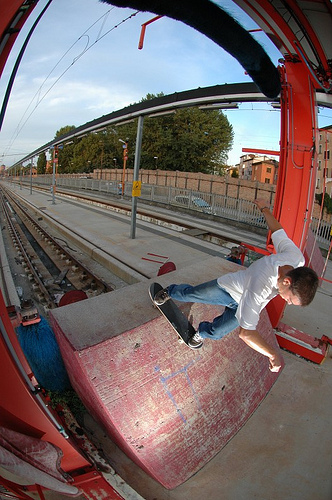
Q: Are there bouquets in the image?
A: No, there are no bouquets.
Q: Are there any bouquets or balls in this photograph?
A: No, there are no bouquets or balls.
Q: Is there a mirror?
A: No, there are no mirrors.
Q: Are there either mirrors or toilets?
A: No, there are no mirrors or toilets.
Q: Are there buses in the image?
A: No, there are no buses.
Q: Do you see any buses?
A: No, there are no buses.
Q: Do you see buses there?
A: No, there are no buses.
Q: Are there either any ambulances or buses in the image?
A: No, there are no buses or ambulances.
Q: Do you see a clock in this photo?
A: No, there are no clocks.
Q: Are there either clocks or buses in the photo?
A: No, there are no clocks or buses.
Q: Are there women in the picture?
A: No, there are no women.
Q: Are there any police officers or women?
A: No, there are no women or police officers.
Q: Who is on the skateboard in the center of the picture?
A: The boy is on the skateboard.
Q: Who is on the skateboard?
A: The boy is on the skateboard.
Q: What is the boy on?
A: The boy is on the skateboard.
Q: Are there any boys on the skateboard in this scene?
A: Yes, there is a boy on the skateboard.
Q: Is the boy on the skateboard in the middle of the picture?
A: Yes, the boy is on the skateboard.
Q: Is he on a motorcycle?
A: No, the boy is on the skateboard.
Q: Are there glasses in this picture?
A: No, there are no glasses.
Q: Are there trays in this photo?
A: No, there are no trays.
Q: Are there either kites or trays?
A: No, there are no trays or kites.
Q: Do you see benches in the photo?
A: No, there are no benches.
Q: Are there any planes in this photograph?
A: No, there are no planes.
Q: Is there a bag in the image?
A: No, there are no bags.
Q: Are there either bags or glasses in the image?
A: No, there are no bags or glasses.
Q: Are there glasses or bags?
A: No, there are no bags or glasses.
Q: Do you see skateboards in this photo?
A: Yes, there is a skateboard.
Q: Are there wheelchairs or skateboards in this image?
A: Yes, there is a skateboard.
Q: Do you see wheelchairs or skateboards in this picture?
A: Yes, there is a skateboard.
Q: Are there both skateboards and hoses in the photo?
A: No, there is a skateboard but no hoses.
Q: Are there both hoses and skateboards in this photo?
A: No, there is a skateboard but no hoses.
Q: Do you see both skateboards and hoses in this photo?
A: No, there is a skateboard but no hoses.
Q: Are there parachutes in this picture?
A: No, there are no parachutes.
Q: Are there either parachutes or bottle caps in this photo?
A: No, there are no parachutes or bottle caps.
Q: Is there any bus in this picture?
A: No, there are no buses.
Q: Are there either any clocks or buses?
A: No, there are no buses or clocks.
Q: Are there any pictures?
A: No, there are no pictures.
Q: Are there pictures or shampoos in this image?
A: No, there are no pictures or shampoos.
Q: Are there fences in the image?
A: Yes, there is a fence.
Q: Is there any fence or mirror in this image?
A: Yes, there is a fence.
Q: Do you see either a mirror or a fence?
A: Yes, there is a fence.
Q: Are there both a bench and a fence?
A: No, there is a fence but no benches.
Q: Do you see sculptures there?
A: No, there are no sculptures.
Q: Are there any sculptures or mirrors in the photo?
A: No, there are no sculptures or mirrors.